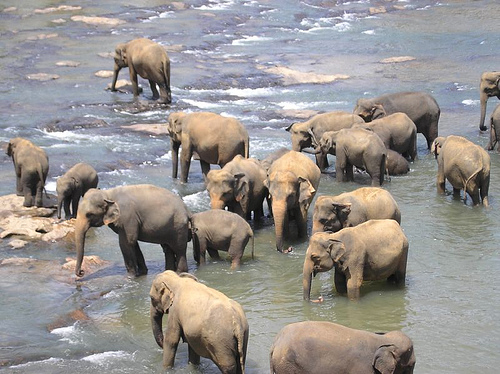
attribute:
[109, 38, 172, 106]
elephant — standing, drinking water, gray, alone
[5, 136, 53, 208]
elephant — gray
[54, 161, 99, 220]
elephant — standing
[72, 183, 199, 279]
elephant — standing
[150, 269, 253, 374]
elephant — standing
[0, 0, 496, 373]
water — shallow, moving, dirty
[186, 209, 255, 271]
elephant — a baby, young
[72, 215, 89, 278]
trunk — long, gray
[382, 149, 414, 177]
elephant — sitting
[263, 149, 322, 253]
elephant — dirty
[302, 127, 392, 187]
elephant — young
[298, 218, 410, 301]
elephant — drinking water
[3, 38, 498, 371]
elephants — in a group, standing